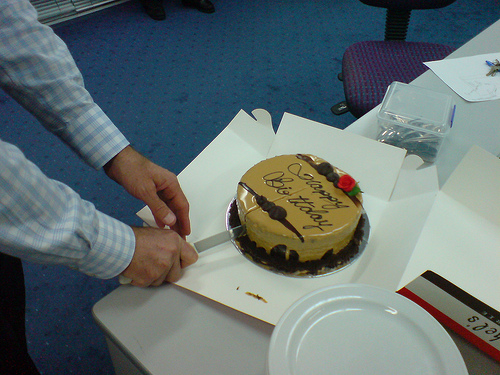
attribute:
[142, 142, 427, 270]
box — white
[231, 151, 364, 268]
cake — dark, yellow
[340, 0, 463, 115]
chair — purple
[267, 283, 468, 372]
plate — white, round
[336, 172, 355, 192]
rose — red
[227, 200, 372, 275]
base — brown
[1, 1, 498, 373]
carpet — blue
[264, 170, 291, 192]
letter — black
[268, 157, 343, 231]
letter — black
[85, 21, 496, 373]
table — long, white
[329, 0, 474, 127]
chair — purple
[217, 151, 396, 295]
cake — round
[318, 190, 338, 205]
letter — black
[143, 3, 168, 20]
shoe — black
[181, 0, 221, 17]
shoe — black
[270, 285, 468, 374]
dish — white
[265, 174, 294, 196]
letter — black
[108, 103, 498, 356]
box — white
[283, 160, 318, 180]
letter — black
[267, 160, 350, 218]
lettering — black